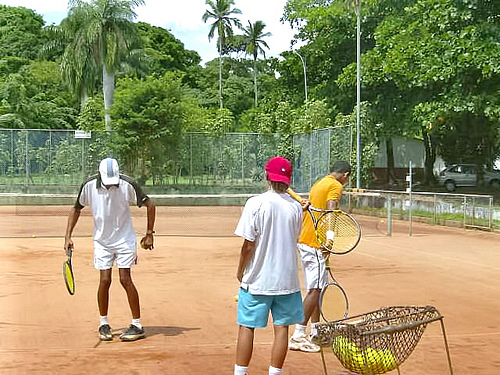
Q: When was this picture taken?
A: Daytime.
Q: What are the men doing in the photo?
A: Preparing to hit tennis balls.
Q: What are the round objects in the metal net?
A: Tennis balls.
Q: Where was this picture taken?
A: Tennis court.